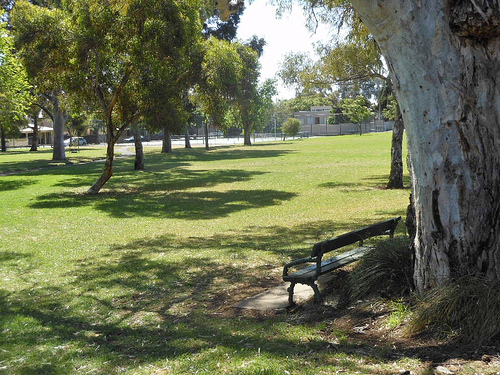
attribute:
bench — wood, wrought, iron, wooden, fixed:
[278, 216, 404, 304]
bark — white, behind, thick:
[360, 5, 498, 293]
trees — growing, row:
[3, 0, 277, 201]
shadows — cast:
[0, 136, 296, 221]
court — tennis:
[159, 125, 309, 146]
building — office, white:
[298, 106, 383, 138]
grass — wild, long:
[350, 237, 499, 350]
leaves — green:
[1, 0, 273, 136]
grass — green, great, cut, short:
[9, 131, 412, 372]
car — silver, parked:
[61, 138, 86, 149]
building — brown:
[48, 117, 146, 142]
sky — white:
[217, 5, 347, 102]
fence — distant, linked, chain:
[294, 122, 398, 137]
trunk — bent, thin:
[85, 97, 122, 201]